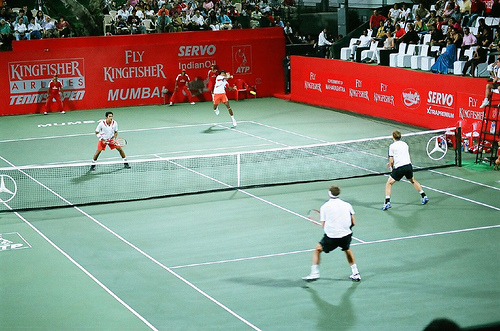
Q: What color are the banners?
A: Red.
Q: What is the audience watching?
A: Tennis match.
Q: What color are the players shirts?
A: White.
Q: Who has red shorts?
A: Guys in back.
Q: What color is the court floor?
A: Green.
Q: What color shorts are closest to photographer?
A: Black.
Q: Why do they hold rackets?
A: Tennis.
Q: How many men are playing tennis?
A: Four.